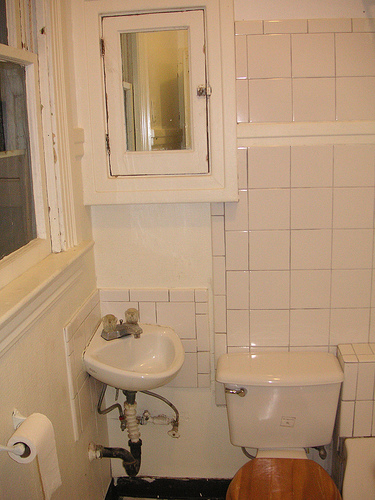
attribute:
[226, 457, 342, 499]
toilet lid — wooden, shiny, brown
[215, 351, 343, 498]
toilet — white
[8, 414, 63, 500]
toilet paper — white, rolled, half roll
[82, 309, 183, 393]
corner sink — white, porcelain, small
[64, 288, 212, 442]
walls — plastered, white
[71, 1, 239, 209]
medicine cabinet — wooden, white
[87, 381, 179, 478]
plumbing — exposed, rusty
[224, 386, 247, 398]
flush handle — metal, chrome, silver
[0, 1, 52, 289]
window — old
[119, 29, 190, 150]
mirror — framed, old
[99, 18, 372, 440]
tile — white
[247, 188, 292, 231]
tile — white, square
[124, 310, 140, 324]
knob — plastic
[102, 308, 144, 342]
faucet — metal, chrome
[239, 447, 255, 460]
pipe — silver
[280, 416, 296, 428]
sticker — small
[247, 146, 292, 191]
tile — white, square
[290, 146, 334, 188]
tile — white, square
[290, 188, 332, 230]
tile — white, square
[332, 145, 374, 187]
tile — white, square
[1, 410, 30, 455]
toilet paper holder — white